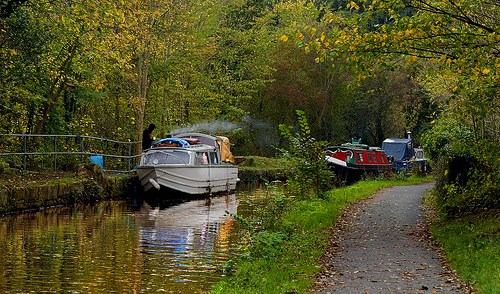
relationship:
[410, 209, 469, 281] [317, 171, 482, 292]
leaves lining path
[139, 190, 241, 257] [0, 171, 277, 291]
boat reflection in water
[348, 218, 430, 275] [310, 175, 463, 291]
leaves on road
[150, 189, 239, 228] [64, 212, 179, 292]
reflection on water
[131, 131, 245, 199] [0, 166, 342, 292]
boat in water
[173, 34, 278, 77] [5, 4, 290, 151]
leaves on tree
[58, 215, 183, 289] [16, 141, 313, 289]
water in river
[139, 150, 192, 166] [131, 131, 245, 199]
windshield on boat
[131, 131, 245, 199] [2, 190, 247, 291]
boat on water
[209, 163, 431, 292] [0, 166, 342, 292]
grass by water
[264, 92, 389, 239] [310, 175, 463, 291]
bush by road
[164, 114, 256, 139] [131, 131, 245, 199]
smoke above boat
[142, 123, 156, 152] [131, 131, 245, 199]
person by boat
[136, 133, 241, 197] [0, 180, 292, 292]
boat traveling by river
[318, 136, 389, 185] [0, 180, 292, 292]
boat traveling by river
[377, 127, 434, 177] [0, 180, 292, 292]
boat traveling by river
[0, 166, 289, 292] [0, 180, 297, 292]
river filled with water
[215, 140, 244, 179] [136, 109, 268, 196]
back of boat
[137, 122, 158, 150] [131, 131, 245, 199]
person standing by boat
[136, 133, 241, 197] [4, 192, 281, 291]
boat in canal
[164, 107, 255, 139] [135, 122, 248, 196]
smoke coming from boat